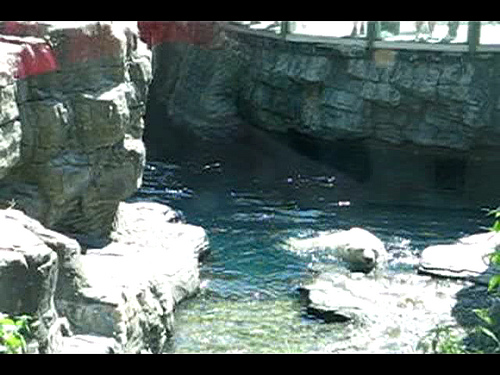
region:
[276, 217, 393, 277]
A polar bear in water at a zoo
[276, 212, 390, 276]
A polar bear in water at a zoo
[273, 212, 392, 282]
A polar bear in water at a zoo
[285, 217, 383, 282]
A polar bear in water at a zoo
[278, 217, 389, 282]
A polar bear in water at a zoo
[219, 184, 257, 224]
the water in a zoo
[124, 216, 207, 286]
a ledge in a zoo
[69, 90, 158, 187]
a cliff in a zoo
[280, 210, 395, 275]
a polar bear in the zoo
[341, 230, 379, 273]
the head of a bear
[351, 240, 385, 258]
the eyes of a bear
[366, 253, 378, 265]
the nose of a bear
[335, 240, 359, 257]
the ears of a bear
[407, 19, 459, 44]
the legs of some people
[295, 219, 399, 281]
a bear in the water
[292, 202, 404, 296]
a bear in the water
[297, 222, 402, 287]
a bear in the water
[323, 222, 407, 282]
a bear in the water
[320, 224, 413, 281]
a bear in the water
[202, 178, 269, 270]
the water is blue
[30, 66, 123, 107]
cracks in a rock surface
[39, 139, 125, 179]
cracks in a rock surface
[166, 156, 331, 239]
trickling water in a river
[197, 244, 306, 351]
blue and green water in a river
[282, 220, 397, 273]
a polar bear in the water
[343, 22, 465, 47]
the feet of people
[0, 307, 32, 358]
green foliage in an enclosement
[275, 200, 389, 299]
this is a bear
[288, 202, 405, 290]
it is a polar bear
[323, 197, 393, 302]
the polar bear is white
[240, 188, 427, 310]
the bear is in water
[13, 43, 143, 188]
brown rock on side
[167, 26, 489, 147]
brown rock in back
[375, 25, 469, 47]
these are peoples feet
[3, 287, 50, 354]
leafs next to rocks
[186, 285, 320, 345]
shallow water near bear